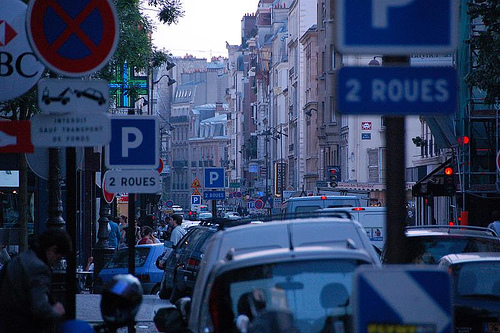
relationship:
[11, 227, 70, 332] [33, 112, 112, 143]
man standing under sign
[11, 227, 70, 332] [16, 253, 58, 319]
man wearing shirt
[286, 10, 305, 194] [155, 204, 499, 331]
building next to road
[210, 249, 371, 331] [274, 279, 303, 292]
mirror inside truck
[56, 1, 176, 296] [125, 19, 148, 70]
tree has leaves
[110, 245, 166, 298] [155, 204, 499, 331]
car on road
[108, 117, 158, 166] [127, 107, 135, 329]
sign attached to pole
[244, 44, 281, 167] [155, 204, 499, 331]
building next to road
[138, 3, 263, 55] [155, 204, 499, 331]
sky above road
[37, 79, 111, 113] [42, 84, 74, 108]
sign with truck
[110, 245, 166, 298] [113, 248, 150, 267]
car has windshield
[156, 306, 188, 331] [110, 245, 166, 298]
mirror on side of car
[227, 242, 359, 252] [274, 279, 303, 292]
rack on top of truck